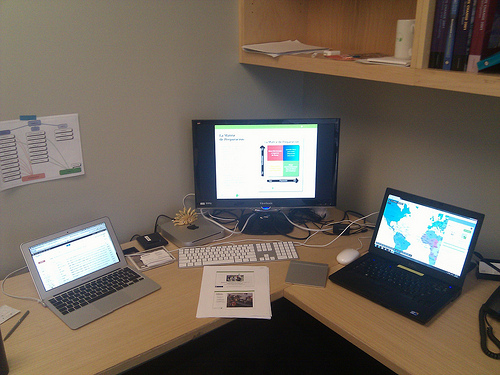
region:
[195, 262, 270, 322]
Papers on the desk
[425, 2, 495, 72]
Books on the shelf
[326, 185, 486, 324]
Black laptop on the table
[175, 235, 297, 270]
White keyboard on the table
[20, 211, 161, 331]
Silver laptop on the table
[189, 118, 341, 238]
lcd monitor on desk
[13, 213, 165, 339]
silver laptop on desk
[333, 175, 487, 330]
black laptop on wooden desk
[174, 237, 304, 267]
computer keyboard with white keys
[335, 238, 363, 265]
white mouse connected to computer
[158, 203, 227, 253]
apple product on desk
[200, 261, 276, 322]
manual on desk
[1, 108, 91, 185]
diagram paper on wall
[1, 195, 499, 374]
wooden desk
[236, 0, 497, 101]
wooden bookshelf with books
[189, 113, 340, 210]
center computer monitor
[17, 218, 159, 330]
left silver laptop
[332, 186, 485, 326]
right black laptop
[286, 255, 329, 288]
silver mouse track pad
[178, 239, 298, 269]
silver and white keyboard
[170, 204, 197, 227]
flower sitting on top of an apple product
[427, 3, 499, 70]
books sitting in the bookcase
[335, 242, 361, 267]
white and clear apple mouse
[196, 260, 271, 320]
report sitting in front of keyboard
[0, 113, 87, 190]
paper taped to the wall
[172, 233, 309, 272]
white keyboard on table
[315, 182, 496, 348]
black lap top on table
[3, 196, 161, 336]
silver lap top on table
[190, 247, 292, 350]
papers on table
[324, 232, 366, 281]
white mouse on table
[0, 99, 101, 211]
paper stuck on wall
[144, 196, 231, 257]
external hard drive on table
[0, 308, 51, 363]
pen on table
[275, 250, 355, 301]
hand pad on table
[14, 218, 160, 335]
The laptop is silver.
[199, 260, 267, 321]
Papers are on the desk.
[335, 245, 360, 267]
The mouse is white.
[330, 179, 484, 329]
The laptop is black.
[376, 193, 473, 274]
A map is on the screen.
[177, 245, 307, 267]
The keys are white.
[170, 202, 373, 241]
Wires are under the monitor.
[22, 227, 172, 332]
The laptop is open.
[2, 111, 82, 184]
A chart is on the wall.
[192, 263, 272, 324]
The paper is white.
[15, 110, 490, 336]
three computers on desk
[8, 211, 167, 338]
open silver laptop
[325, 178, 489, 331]
open black laptop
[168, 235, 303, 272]
silver and white computer keyboard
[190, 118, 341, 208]
the black monitor is turned on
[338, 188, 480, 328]
the black laptop is turned on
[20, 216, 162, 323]
the black and grey laptop is turned on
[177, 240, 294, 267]
the keyboard is silver and white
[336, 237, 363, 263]
the computer mouse is white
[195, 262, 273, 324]
A peice of paper was left in front of the keyboard.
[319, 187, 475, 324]
A black laptop was left open on the desk.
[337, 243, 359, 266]
A white computer mouse is next to the laptop.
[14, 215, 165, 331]
A silver laptop is left open on the deskk.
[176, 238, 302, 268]
A keyboard with white keys is on the desk.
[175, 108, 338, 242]
A black computer monitor is on the desk.